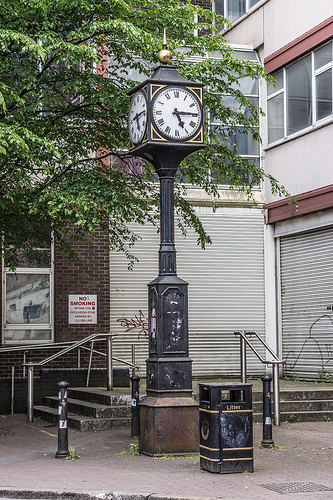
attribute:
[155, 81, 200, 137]
clock — white, showing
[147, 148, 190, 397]
post — black, iron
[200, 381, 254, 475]
trash can — metal, black, square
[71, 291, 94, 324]
sign — red, white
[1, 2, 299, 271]
tree — green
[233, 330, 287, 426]
railing — metal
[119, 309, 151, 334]
graffiti — red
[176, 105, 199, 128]
hands — black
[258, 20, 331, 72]
frame — red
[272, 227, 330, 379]
door — metal, rolling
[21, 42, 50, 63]
leaves — green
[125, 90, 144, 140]
clock — showing